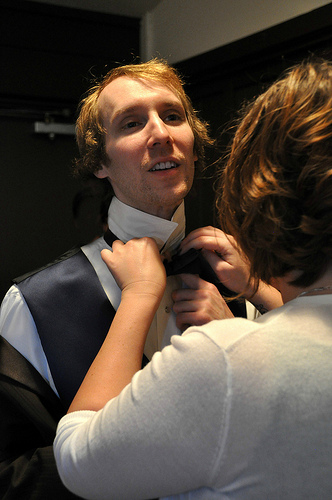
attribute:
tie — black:
[104, 228, 202, 276]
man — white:
[1, 55, 264, 499]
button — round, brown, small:
[163, 304, 175, 314]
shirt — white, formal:
[1, 195, 262, 398]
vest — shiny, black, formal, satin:
[13, 244, 249, 408]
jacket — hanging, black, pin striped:
[0, 335, 85, 498]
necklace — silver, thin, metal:
[297, 285, 332, 299]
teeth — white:
[151, 159, 179, 170]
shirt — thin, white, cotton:
[53, 293, 331, 499]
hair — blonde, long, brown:
[75, 55, 215, 182]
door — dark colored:
[1, 106, 114, 303]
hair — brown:
[200, 47, 330, 305]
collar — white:
[108, 196, 186, 256]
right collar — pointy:
[107, 196, 180, 255]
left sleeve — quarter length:
[53, 331, 227, 498]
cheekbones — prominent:
[109, 120, 196, 162]